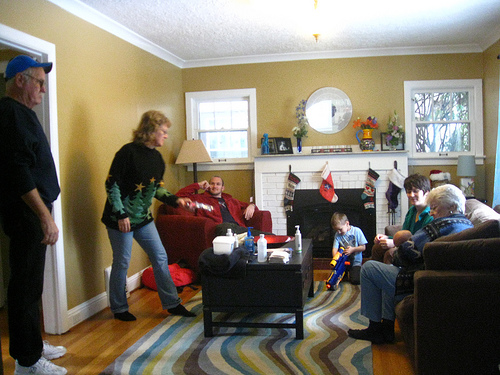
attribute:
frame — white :
[391, 71, 489, 162]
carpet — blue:
[93, 247, 374, 374]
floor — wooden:
[3, 267, 417, 375]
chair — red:
[155, 187, 273, 292]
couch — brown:
[382, 190, 499, 374]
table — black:
[201, 226, 316, 341]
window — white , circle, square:
[178, 84, 262, 173]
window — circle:
[306, 83, 355, 141]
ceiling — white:
[41, 0, 498, 70]